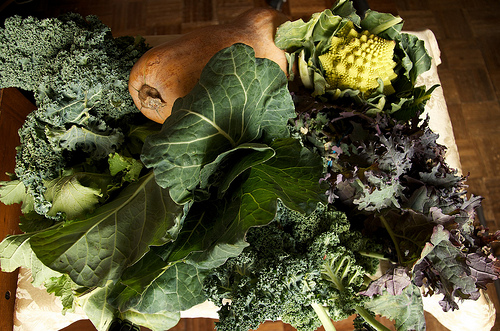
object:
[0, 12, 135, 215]
broccoli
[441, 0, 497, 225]
flooring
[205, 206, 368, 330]
broccoli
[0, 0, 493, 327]
table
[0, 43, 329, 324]
lettuce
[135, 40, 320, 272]
leaf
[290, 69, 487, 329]
leaves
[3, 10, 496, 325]
vegetables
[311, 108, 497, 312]
lettuce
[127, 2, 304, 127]
pumpkin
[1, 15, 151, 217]
broccoli sticks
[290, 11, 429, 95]
vegetable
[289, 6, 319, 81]
leaves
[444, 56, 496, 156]
table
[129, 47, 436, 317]
vegetables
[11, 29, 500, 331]
fabric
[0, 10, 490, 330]
garden